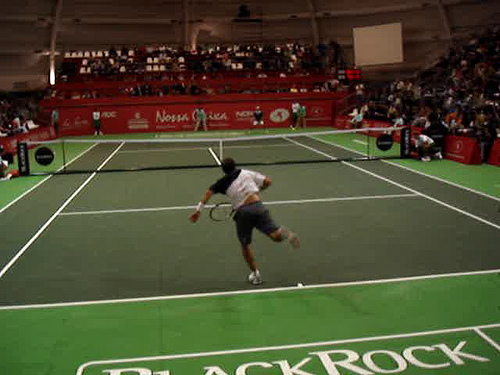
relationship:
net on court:
[61, 135, 360, 181] [61, 132, 495, 278]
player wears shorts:
[238, 92, 280, 151] [250, 119, 273, 129]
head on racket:
[210, 201, 227, 218] [212, 186, 265, 223]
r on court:
[312, 349, 361, 374] [61, 132, 495, 278]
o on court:
[351, 338, 407, 371] [61, 132, 495, 278]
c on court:
[389, 330, 433, 372] [61, 132, 495, 278]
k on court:
[433, 329, 483, 371] [61, 132, 495, 278]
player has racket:
[238, 92, 280, 151] [212, 186, 265, 223]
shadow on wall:
[179, 19, 242, 47] [3, 1, 342, 42]